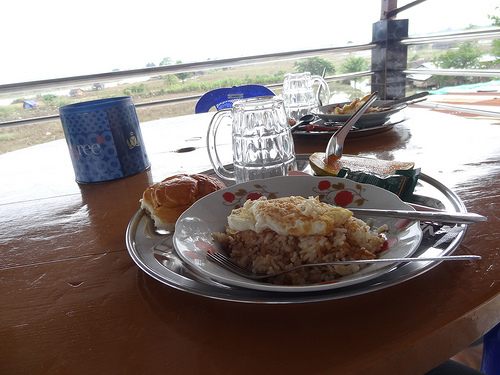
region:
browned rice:
[202, 222, 386, 287]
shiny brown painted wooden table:
[5, 84, 499, 372]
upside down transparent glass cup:
[201, 91, 315, 178]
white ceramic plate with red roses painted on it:
[164, 171, 424, 298]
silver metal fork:
[202, 244, 481, 295]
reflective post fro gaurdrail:
[373, 0, 413, 105]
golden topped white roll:
[136, 170, 231, 232]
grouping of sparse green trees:
[304, 36, 499, 94]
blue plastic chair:
[195, 76, 280, 118]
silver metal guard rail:
[379, 28, 496, 87]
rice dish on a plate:
[201, 190, 393, 287]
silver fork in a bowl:
[195, 248, 492, 284]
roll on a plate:
[136, 164, 226, 238]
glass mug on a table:
[207, 89, 299, 188]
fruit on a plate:
[299, 141, 434, 203]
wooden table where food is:
[10, 182, 111, 354]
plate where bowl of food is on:
[107, 223, 174, 290]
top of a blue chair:
[188, 82, 287, 109]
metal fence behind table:
[410, 20, 498, 108]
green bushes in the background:
[148, 79, 198, 96]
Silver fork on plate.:
[213, 241, 379, 302]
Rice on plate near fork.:
[260, 237, 323, 292]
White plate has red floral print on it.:
[219, 170, 382, 260]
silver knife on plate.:
[347, 188, 480, 238]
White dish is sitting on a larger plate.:
[171, 212, 401, 303]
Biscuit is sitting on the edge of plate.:
[137, 165, 239, 267]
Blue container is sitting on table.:
[38, 80, 147, 185]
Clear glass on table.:
[216, 80, 293, 204]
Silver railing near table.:
[126, 46, 290, 77]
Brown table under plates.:
[48, 223, 182, 358]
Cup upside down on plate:
[121, 98, 468, 321]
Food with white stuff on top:
[200, 193, 395, 298]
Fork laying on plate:
[198, 226, 477, 299]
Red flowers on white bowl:
[197, 181, 391, 227]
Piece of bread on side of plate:
[126, 162, 242, 243]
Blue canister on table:
[51, 89, 155, 186]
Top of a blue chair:
[191, 83, 278, 117]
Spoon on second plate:
[284, 103, 317, 142]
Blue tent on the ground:
[11, 94, 42, 114]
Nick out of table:
[58, 273, 93, 293]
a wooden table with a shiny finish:
[1, 153, 133, 373]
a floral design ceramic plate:
[174, 173, 421, 290]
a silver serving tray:
[122, 223, 203, 301]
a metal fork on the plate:
[205, 246, 481, 276]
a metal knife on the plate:
[341, 205, 483, 222]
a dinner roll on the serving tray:
[138, 170, 223, 230]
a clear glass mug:
[207, 95, 297, 182]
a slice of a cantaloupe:
[309, 148, 419, 194]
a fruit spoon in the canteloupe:
[327, 93, 377, 160]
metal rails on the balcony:
[404, 26, 499, 116]